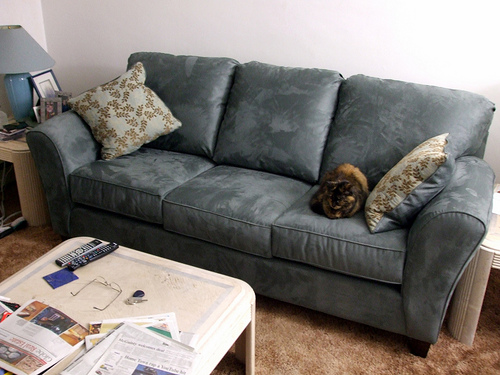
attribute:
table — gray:
[0, 78, 90, 229]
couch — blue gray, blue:
[28, 48, 496, 355]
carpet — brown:
[1, 222, 497, 373]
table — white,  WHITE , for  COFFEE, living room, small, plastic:
[2, 235, 256, 374]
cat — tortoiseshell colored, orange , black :
[306, 160, 373, 218]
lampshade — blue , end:
[1, 24, 55, 73]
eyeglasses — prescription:
[67, 272, 122, 313]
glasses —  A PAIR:
[62, 275, 128, 313]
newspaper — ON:
[0, 314, 196, 374]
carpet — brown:
[261, 305, 434, 373]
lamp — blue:
[8, 13, 108, 187]